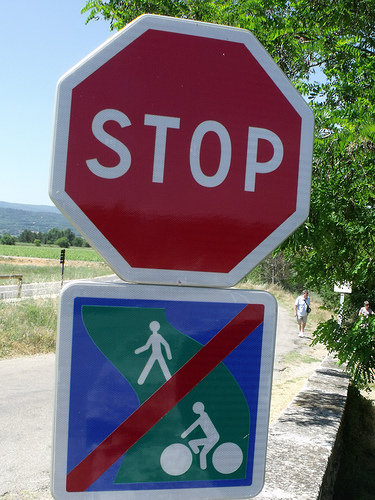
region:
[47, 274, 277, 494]
The sign below the stop sign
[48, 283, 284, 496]
The sign with a red line through it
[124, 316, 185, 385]
The person walking on the sign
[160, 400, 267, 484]
The person riding a bike on the sign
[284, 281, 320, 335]
The man in the background walking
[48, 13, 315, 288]
A white and red STOP sign.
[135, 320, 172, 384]
A white stick figure walking.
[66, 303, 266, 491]
A red slash through the bottom sign.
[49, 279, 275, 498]
White trimmed rectangle sign with white figures on it.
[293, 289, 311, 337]
A man in a blue shirt and white shoes walking.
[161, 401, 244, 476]
White stick figure riding a bike.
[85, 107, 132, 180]
White S in STOP.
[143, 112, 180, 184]
White T in STOP.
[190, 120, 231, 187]
White O in STOP.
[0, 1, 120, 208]
A blue sky.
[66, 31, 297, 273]
a sign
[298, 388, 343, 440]
a shadow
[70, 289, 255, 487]
a square sign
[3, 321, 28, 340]
the grass is brown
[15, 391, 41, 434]
the sidewalk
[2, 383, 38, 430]
sidewalk is grey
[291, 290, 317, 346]
a person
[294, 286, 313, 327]
a person standing wearing a white shirt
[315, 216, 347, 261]
leaves are green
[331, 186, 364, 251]
tree with green leaves